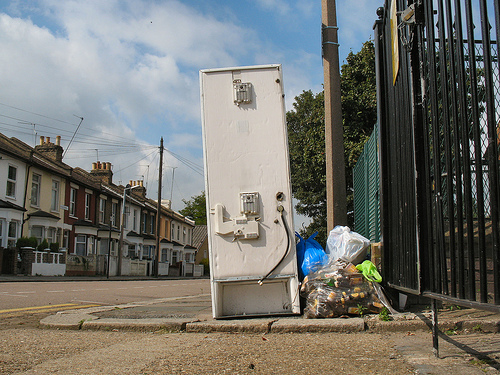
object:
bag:
[293, 224, 388, 322]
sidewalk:
[0, 278, 210, 318]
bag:
[293, 229, 330, 276]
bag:
[325, 223, 373, 269]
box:
[188, 61, 304, 321]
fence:
[377, 1, 500, 352]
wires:
[0, 103, 203, 184]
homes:
[0, 133, 201, 277]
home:
[0, 132, 33, 282]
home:
[117, 179, 150, 281]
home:
[18, 144, 71, 274]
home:
[55, 163, 125, 279]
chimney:
[34, 135, 65, 162]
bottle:
[339, 303, 365, 314]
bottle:
[325, 286, 342, 303]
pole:
[316, 0, 349, 246]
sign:
[314, 21, 339, 62]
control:
[231, 79, 255, 106]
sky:
[2, 0, 498, 135]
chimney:
[90, 160, 117, 184]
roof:
[79, 157, 123, 184]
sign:
[380, 0, 407, 85]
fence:
[348, 124, 381, 245]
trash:
[291, 221, 382, 321]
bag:
[297, 258, 387, 317]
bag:
[353, 258, 383, 284]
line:
[1, 297, 104, 317]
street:
[0, 278, 215, 374]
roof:
[25, 131, 74, 165]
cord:
[258, 212, 293, 287]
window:
[4, 163, 19, 200]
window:
[49, 176, 59, 215]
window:
[65, 185, 79, 217]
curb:
[38, 315, 500, 334]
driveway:
[0, 328, 499, 375]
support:
[427, 298, 446, 357]